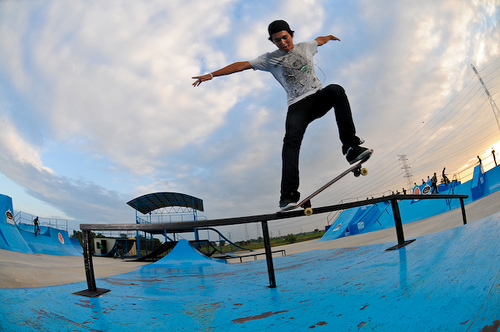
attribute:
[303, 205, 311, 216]
wheels — white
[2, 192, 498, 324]
skatepark — grey, large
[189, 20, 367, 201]
boy — skating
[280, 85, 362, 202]
jeans — black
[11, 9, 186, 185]
sky — blue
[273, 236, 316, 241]
grass — green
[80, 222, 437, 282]
ramp — black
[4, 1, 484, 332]
picture — outdoors, daytime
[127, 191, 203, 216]
canopy — curved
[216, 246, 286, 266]
bench — black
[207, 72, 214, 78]
bracelet — silver